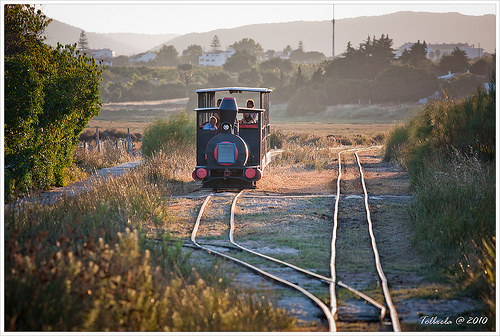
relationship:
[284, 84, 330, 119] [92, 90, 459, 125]
bush on hill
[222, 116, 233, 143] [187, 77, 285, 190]
light on trolley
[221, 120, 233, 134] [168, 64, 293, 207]
light on front of train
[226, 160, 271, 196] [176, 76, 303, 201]
wheel on bottom of train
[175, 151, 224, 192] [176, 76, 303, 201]
wheel on bottom of train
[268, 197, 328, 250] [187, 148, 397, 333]
grass between tracks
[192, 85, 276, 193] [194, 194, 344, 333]
train in tracks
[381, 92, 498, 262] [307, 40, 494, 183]
bush on a hill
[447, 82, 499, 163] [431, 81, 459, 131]
bush on a bush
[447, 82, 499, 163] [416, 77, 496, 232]
bush on a hill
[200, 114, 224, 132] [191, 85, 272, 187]
man in front of train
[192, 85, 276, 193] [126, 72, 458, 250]
train on ground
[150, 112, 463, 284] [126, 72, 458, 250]
tracks on ground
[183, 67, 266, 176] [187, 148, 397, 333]
train on tracks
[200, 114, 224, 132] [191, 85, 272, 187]
man on train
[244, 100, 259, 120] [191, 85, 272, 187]
people on train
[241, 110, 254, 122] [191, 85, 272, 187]
people on train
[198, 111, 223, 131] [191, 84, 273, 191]
man in front trolley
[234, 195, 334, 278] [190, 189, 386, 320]
ground between tracks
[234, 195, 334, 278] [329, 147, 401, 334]
ground between tracks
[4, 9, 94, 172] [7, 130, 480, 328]
bush on a hill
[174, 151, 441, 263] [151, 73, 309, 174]
tracks before train